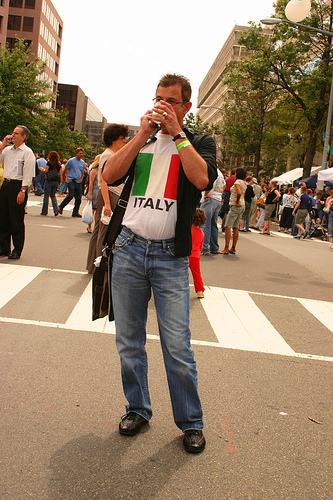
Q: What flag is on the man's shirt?
A: Italian.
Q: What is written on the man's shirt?
A: Italy.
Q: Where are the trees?
A: On the side of the streets.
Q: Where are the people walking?
A: On the street.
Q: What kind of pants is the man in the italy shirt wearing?
A: Jeans.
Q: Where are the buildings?
A: On the sides of the street.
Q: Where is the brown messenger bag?
A: On the man in the italy shirt shoulder.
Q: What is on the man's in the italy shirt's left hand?
A: A ring.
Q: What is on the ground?
A: Painted white lines.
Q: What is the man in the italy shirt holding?
A: A glass.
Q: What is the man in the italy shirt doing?
A: Drinking.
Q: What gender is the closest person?
A: Male.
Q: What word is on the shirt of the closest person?
A: ITALY.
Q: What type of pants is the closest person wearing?
A: Blue jeans.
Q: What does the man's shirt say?
A: Italy.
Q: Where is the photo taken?
A: On a city street.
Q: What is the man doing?
A: Drinking and talking on a cell phone.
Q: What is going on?
A: A street festival.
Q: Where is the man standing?
A: In the cross walk.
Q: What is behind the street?
A: A festival.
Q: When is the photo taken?
A: Daytime.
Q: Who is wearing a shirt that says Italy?
A: The man in the foreground.